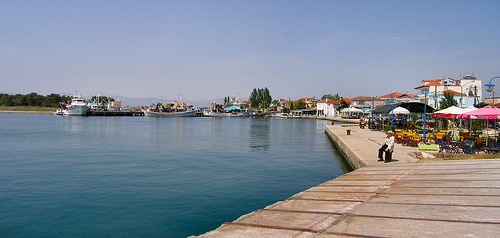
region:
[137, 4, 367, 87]
this is the sky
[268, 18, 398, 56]
the sky is blue in color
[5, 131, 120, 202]
this is a water body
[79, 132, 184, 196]
the water is calm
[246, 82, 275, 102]
this is a tree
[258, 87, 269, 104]
the leaves are green in color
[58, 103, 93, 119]
this is a ship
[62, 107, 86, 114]
the ship is white in color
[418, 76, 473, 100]
this is a building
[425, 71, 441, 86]
the roof is red in color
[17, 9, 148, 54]
this is the sky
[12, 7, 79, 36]
the sky is blue in color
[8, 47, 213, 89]
the sky has some clouds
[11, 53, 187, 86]
the clouds are white in color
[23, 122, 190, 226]
this is the water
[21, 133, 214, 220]
the water is blue in color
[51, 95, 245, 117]
these are some boats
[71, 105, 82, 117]
the boat is white in color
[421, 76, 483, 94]
this is a building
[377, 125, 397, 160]
this is a man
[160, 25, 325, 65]
the sky is blue in color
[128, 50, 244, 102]
the sky has some clouds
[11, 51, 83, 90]
the clouds are white in color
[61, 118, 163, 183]
the water is blue in color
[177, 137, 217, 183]
part of a water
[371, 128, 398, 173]
THE PERSON IS SITTING AT THE WATER'S EDGE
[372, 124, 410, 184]
THE PERSON IS STARING AT THE WATER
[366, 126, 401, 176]
THE PERSON IS WEARING BLACK PANTS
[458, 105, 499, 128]
THIS UMBRELLA IS PINK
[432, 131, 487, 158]
THESE CHAIRS ARE BLUE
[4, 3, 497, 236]
THE DAY LOOKS NICE AND SUNNY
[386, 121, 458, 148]
THESE CHAIRS ARE YELLOW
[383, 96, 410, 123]
THIS UMBRELLA IS WHITE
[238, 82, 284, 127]
THIS IS A CLUMP OF TREES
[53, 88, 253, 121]
THESE ARE BOATS ON THE WATER